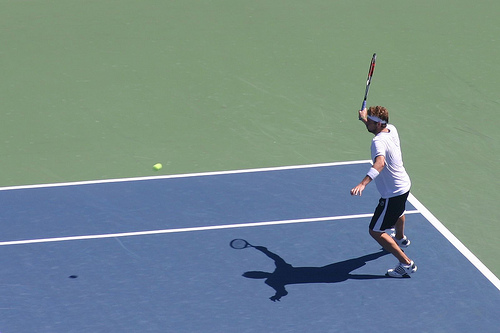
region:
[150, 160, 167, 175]
The ball in the air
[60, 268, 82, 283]
The shadow of the tennis ball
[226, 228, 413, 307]
Shadow of the man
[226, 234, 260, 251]
The shadow of the racket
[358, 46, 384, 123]
The racket in the man's hand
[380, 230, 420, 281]
The white tennis shoes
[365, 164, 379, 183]
The wristband on the man's left arm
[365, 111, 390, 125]
The headband of the man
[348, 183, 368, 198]
The open left hand of the man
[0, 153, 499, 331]
The blue portion of the tennis court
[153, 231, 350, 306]
the court is blue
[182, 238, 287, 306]
the court is blue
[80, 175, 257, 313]
the court is blue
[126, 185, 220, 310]
the court is blue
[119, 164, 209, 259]
the court is blue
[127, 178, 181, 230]
the court is blue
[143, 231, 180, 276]
the court is blue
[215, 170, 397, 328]
shadow is cast on the ground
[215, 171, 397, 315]
shadow is casted on the ground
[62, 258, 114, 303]
ball shadow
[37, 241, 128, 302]
ball shadow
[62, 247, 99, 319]
ball shadow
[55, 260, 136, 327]
ball shadow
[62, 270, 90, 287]
ball shadow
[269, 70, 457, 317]
man wearing white shirt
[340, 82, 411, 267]
man wearing white shirt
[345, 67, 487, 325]
man wearing white shirt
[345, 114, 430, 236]
man wearing white shirtman wearing white shirt